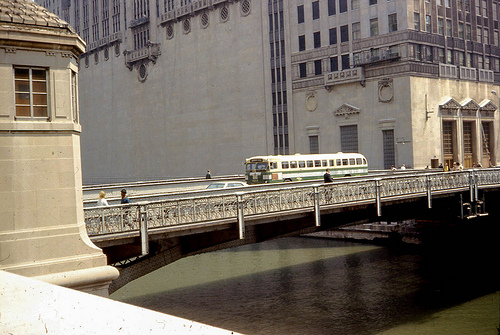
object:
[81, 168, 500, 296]
bridge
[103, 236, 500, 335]
water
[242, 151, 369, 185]
bus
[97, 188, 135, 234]
two people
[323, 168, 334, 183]
man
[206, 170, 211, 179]
person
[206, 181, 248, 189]
car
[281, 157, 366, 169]
windows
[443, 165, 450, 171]
shirt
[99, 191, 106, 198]
hair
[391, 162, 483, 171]
people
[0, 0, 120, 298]
building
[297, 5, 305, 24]
window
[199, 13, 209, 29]
designs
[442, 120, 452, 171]
door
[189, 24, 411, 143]
structure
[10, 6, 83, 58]
structures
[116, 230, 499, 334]
shadow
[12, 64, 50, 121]
eight panes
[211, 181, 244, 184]
top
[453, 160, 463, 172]
brunette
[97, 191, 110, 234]
blonde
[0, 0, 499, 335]
photograph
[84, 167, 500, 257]
city bridge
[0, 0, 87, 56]
roof